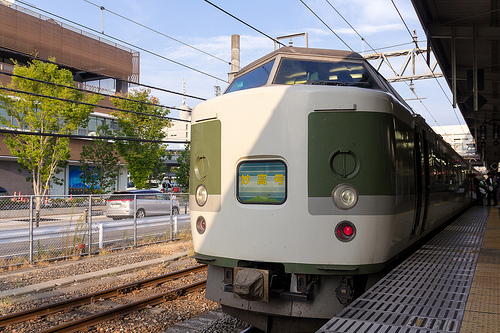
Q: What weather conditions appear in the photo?
A: It is clear.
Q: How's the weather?
A: It is clear.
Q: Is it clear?
A: Yes, it is clear.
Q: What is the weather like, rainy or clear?
A: It is clear.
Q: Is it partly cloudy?
A: No, it is clear.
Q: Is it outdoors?
A: Yes, it is outdoors.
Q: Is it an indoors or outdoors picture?
A: It is outdoors.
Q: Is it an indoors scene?
A: No, it is outdoors.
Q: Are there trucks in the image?
A: No, there are no trucks.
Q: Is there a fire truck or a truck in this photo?
A: No, there are no trucks or fire trucks.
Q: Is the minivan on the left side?
A: Yes, the minivan is on the left of the image.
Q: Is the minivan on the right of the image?
A: No, the minivan is on the left of the image.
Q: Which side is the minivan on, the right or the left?
A: The minivan is on the left of the image.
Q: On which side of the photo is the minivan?
A: The minivan is on the left of the image.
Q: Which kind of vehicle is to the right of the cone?
A: The vehicle is a minivan.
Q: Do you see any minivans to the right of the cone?
A: Yes, there is a minivan to the right of the cone.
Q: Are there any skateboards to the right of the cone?
A: No, there is a minivan to the right of the cone.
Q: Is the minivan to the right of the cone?
A: Yes, the minivan is to the right of the cone.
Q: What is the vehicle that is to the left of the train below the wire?
A: The vehicle is a minivan.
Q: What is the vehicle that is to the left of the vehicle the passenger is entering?
A: The vehicle is a minivan.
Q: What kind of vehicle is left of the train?
A: The vehicle is a minivan.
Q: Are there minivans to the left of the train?
A: Yes, there is a minivan to the left of the train.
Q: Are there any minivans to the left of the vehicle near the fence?
A: Yes, there is a minivan to the left of the train.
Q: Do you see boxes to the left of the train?
A: No, there is a minivan to the left of the train.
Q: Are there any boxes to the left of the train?
A: No, there is a minivan to the left of the train.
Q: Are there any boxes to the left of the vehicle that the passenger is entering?
A: No, there is a minivan to the left of the train.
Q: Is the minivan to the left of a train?
A: Yes, the minivan is to the left of a train.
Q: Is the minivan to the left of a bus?
A: No, the minivan is to the left of a train.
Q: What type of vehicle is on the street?
A: The vehicle is a minivan.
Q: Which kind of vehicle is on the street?
A: The vehicle is a minivan.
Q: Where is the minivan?
A: The minivan is on the street.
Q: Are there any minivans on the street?
A: Yes, there is a minivan on the street.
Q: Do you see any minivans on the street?
A: Yes, there is a minivan on the street.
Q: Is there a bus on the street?
A: No, there is a minivan on the street.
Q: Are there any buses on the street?
A: No, there is a minivan on the street.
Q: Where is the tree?
A: The tree is on the street.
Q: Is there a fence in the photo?
A: Yes, there is a fence.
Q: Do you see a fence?
A: Yes, there is a fence.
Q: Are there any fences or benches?
A: Yes, there is a fence.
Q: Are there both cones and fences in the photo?
A: Yes, there are both a fence and cones.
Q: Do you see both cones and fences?
A: Yes, there are both a fence and cones.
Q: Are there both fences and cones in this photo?
A: Yes, there are both a fence and cones.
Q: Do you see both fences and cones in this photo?
A: Yes, there are both a fence and cones.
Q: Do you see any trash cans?
A: No, there are no trash cans.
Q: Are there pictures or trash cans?
A: No, there are no trash cans or pictures.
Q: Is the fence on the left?
A: Yes, the fence is on the left of the image.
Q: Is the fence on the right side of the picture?
A: No, the fence is on the left of the image.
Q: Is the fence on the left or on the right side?
A: The fence is on the left of the image.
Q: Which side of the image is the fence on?
A: The fence is on the left of the image.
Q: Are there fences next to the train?
A: Yes, there is a fence next to the train.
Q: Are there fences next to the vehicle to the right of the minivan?
A: Yes, there is a fence next to the train.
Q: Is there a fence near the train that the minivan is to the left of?
A: Yes, there is a fence near the train.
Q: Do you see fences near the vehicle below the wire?
A: Yes, there is a fence near the train.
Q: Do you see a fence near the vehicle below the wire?
A: Yes, there is a fence near the train.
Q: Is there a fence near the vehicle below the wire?
A: Yes, there is a fence near the train.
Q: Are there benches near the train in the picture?
A: No, there is a fence near the train.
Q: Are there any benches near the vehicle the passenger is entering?
A: No, there is a fence near the train.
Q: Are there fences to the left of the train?
A: Yes, there is a fence to the left of the train.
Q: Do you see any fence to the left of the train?
A: Yes, there is a fence to the left of the train.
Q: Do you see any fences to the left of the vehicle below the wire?
A: Yes, there is a fence to the left of the train.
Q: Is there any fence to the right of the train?
A: No, the fence is to the left of the train.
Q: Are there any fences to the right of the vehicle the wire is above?
A: No, the fence is to the left of the train.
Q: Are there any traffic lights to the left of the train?
A: No, there is a fence to the left of the train.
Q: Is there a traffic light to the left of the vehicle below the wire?
A: No, there is a fence to the left of the train.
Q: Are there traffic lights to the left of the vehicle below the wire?
A: No, there is a fence to the left of the train.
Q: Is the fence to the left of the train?
A: Yes, the fence is to the left of the train.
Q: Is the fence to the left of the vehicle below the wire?
A: Yes, the fence is to the left of the train.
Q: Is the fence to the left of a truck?
A: No, the fence is to the left of the train.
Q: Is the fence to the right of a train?
A: No, the fence is to the left of a train.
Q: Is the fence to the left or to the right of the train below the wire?
A: The fence is to the left of the train.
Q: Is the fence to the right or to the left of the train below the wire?
A: The fence is to the left of the train.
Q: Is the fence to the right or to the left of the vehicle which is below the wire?
A: The fence is to the left of the train.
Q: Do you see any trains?
A: Yes, there is a train.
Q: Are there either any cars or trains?
A: Yes, there is a train.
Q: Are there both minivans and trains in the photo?
A: Yes, there are both a train and a minivan.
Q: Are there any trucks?
A: No, there are no trucks.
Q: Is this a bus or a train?
A: This is a train.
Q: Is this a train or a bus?
A: This is a train.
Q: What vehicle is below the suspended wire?
A: The vehicle is a train.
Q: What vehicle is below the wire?
A: The vehicle is a train.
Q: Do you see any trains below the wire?
A: Yes, there is a train below the wire.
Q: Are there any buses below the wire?
A: No, there is a train below the wire.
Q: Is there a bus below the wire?
A: No, there is a train below the wire.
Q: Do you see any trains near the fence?
A: Yes, there is a train near the fence.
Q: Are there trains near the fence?
A: Yes, there is a train near the fence.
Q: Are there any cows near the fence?
A: No, there is a train near the fence.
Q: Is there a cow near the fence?
A: No, there is a train near the fence.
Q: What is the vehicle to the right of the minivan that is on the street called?
A: The vehicle is a train.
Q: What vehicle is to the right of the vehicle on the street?
A: The vehicle is a train.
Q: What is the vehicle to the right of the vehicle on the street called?
A: The vehicle is a train.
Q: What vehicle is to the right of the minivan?
A: The vehicle is a train.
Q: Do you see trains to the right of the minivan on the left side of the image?
A: Yes, there is a train to the right of the minivan.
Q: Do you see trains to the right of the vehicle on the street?
A: Yes, there is a train to the right of the minivan.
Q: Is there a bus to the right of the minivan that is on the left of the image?
A: No, there is a train to the right of the minivan.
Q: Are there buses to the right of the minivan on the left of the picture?
A: No, there is a train to the right of the minivan.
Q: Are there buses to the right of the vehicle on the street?
A: No, there is a train to the right of the minivan.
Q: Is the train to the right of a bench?
A: No, the train is to the right of the minivan.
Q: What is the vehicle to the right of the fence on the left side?
A: The vehicle is a train.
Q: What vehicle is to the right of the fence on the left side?
A: The vehicle is a train.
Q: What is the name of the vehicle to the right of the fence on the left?
A: The vehicle is a train.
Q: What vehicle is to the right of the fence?
A: The vehicle is a train.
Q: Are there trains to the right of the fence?
A: Yes, there is a train to the right of the fence.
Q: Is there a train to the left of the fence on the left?
A: No, the train is to the right of the fence.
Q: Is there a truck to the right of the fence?
A: No, there is a train to the right of the fence.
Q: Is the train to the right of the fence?
A: Yes, the train is to the right of the fence.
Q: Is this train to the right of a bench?
A: No, the train is to the right of the fence.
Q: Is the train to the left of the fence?
A: No, the train is to the right of the fence.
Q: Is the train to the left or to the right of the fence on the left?
A: The train is to the right of the fence.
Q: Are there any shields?
A: No, there are no shields.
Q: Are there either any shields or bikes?
A: No, there are no shields or bikes.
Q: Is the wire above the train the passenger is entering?
A: Yes, the wire is above the train.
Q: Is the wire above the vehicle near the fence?
A: Yes, the wire is above the train.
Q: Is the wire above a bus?
A: No, the wire is above the train.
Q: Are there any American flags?
A: No, there are no American flags.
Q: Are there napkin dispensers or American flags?
A: No, there are no American flags or napkin dispensers.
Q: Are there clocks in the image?
A: No, there are no clocks.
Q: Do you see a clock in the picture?
A: No, there are no clocks.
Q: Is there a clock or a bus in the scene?
A: No, there are no clocks or buses.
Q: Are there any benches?
A: No, there are no benches.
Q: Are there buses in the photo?
A: No, there are no buses.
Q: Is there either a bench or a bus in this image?
A: No, there are no buses or benches.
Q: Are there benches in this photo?
A: No, there are no benches.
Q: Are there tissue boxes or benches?
A: No, there are no benches or tissue boxes.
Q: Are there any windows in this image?
A: Yes, there is a window.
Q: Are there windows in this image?
A: Yes, there is a window.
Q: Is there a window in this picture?
A: Yes, there is a window.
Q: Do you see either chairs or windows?
A: Yes, there is a window.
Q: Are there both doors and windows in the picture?
A: Yes, there are both a window and a door.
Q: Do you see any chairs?
A: No, there are no chairs.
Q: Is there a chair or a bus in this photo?
A: No, there are no chairs or buses.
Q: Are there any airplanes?
A: No, there are no airplanes.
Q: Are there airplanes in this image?
A: No, there are no airplanes.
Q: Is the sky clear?
A: Yes, the sky is clear.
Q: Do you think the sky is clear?
A: Yes, the sky is clear.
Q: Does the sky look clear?
A: Yes, the sky is clear.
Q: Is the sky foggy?
A: No, the sky is clear.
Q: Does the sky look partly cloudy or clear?
A: The sky is clear.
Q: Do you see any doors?
A: Yes, there is a door.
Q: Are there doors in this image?
A: Yes, there is a door.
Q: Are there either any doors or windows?
A: Yes, there is a door.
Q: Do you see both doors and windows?
A: Yes, there are both a door and a window.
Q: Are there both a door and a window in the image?
A: Yes, there are both a door and a window.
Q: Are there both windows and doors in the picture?
A: Yes, there are both a door and a window.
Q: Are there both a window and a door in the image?
A: Yes, there are both a door and a window.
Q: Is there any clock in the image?
A: No, there are no clocks.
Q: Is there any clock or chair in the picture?
A: No, there are no clocks or chairs.